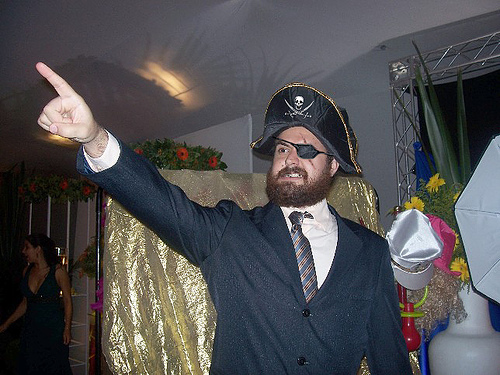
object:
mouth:
[277, 169, 304, 181]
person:
[36, 56, 460, 374]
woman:
[0, 229, 73, 374]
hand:
[35, 59, 104, 145]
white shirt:
[277, 194, 340, 291]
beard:
[261, 166, 340, 206]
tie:
[290, 208, 320, 304]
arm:
[366, 240, 412, 374]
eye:
[274, 143, 287, 152]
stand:
[382, 61, 430, 215]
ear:
[327, 155, 342, 177]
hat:
[249, 83, 371, 179]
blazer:
[79, 121, 422, 374]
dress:
[20, 261, 66, 374]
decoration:
[125, 135, 227, 172]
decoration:
[0, 172, 98, 196]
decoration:
[69, 235, 98, 286]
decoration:
[393, 170, 473, 283]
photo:
[0, 0, 500, 374]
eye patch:
[269, 134, 340, 163]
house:
[0, 0, 500, 374]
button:
[300, 306, 311, 317]